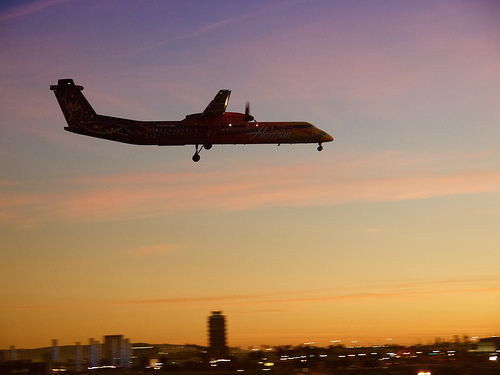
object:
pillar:
[207, 306, 217, 324]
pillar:
[218, 310, 227, 324]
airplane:
[48, 77, 335, 164]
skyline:
[0, 310, 499, 354]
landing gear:
[191, 142, 202, 164]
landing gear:
[316, 143, 324, 152]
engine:
[186, 112, 253, 129]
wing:
[196, 89, 232, 131]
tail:
[49, 78, 96, 136]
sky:
[0, 0, 499, 310]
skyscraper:
[117, 336, 136, 372]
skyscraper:
[87, 337, 102, 371]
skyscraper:
[72, 340, 84, 375]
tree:
[433, 334, 443, 346]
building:
[204, 307, 231, 363]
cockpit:
[287, 121, 314, 131]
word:
[245, 125, 294, 142]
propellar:
[244, 100, 254, 128]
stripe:
[313, 130, 326, 140]